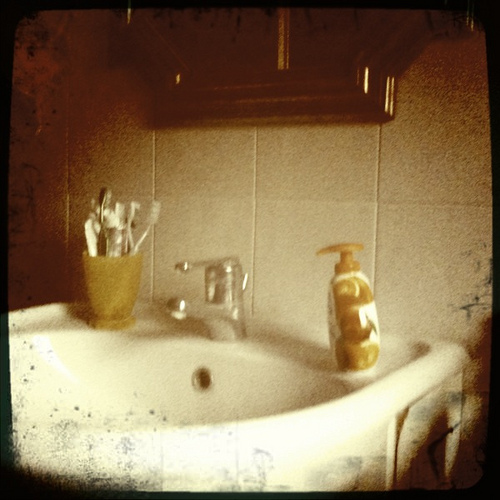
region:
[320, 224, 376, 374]
soap dispenser on sink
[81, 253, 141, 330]
toothbrush holder on sink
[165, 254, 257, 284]
handle on the faucet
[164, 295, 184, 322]
spigot of silver faucet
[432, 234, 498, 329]
dark marks on wall beside sink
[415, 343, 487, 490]
shadow on wall and sink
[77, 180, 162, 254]
toothbrushes in toothbrush holder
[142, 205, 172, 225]
white bristles of toothbrush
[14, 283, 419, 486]
white sink with toothbrush holder on it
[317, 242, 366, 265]
pump on soap dispenser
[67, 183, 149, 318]
yellow toothbrush holder on sink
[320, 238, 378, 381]
soap dispenser on white sink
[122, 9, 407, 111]
mirror above the sink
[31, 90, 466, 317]
white tiles above sink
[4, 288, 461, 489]
white sink with silver faucet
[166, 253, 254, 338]
silver faucet with handle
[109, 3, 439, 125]
frame of mirror above sink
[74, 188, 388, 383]
toothbrush holder and soap dispenser on sink edge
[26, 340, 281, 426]
white interior of sink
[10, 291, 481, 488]
white bathroom sink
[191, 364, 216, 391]
overflow hole in the back of the sink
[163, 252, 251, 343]
silver colored sink faucet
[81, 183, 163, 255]
items for oral care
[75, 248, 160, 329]
gold colored cup on sink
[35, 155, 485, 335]
tiles on the wall behind the sink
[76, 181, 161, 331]
toothpaste and brushes in a glass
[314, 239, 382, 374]
gold colored pump bottle for hand soap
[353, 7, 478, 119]
curved part of the wall mirror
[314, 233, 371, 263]
The top of a soap dispenser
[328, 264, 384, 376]
The body of a soap dispenser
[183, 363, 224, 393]
An empty whole for water to pass through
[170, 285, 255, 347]
The lower half of a water faucet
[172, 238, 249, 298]
The upper half of a water facet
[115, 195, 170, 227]
The upper portions of toothbrushes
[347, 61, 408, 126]
The bottom right corner of a picture frame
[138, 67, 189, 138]
The bottom left corner of a picture frame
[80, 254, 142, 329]
A small yellow cup for holding toothbrushes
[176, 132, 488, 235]
The tile decoration pattern of the wall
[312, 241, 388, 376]
plasric soap dispender with design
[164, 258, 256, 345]
chrome pump water spigot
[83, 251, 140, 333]
maize colored bathroom cup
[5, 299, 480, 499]
white porcelain pedestal sink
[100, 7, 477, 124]
brown wood frame bathroom window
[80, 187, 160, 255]
group of assorted toothbrushes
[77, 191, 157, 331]
bathrom cup with toothbrushes inside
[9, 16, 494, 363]
light color tile wall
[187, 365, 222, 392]
round backsplash hole of sink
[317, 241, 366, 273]
punp of plastic soap dispenser